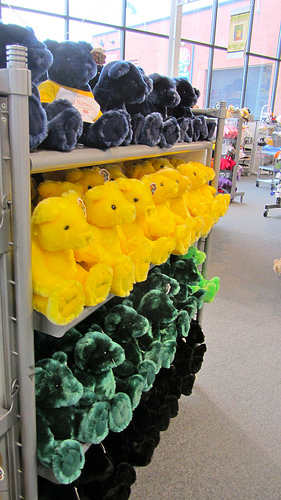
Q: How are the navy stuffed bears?
A: In a row.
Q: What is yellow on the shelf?
A: Bears.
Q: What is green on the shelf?
A: Teddy bears.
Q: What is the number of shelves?
A: 3.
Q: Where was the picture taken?
A: Toy store.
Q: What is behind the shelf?
A: Windows.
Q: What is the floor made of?
A: Carpet.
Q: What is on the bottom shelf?
A: Black bears.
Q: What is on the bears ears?
A: Tag.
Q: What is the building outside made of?
A: Brick.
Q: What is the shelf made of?
A: Metal.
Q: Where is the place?
A: Toy store.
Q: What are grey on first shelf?
A: Teddy bears.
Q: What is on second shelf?
A: Yellow teddy bears.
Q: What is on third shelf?
A: Green teddy bears.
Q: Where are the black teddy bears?
A: Bottom shelf.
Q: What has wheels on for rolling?
A: Stands.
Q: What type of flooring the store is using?
A: Carpet.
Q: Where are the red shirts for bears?
A: Fourth shelf.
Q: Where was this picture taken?
A: In a toy shop.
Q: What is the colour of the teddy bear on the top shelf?
A: Grey.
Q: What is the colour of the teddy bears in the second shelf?
A: Yellow.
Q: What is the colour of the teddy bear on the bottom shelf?
A: Black.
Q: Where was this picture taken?
A: A toy shop.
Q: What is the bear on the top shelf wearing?
A: A shirt.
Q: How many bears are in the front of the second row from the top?
A: Seven.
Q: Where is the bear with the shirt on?
A: The top shelf.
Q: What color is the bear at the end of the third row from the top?
A: Bright green.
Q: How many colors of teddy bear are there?
A: Four.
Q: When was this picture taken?
A: Daytime.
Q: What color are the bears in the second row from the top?
A: Yellow.